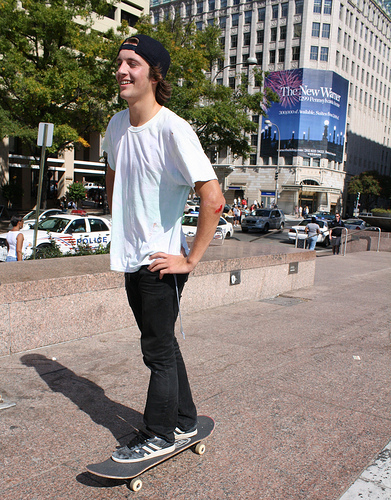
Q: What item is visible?
A: Skateboard.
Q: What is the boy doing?
A: Skateboarding.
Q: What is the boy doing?
A: Skateboarding.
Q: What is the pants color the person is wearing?
A: Black.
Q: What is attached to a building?
A: A banner.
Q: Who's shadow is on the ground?
A: The boys.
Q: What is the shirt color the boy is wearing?
A: White.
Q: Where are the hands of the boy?
A: On the hips.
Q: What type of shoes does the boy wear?
A: Tenna shoes.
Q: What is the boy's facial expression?
A: Smiling.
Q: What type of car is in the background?
A: A police car.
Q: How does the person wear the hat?
A: Backwards.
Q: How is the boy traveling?
A: By skateboard.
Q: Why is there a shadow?
A: Because the sun is shining.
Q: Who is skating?
A: A boy.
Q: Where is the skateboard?
A: On the pavement.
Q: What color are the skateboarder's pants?
A: Black.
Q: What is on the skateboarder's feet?
A: Shoes.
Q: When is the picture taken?
A: In the daytime.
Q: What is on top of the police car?
A: Lights.